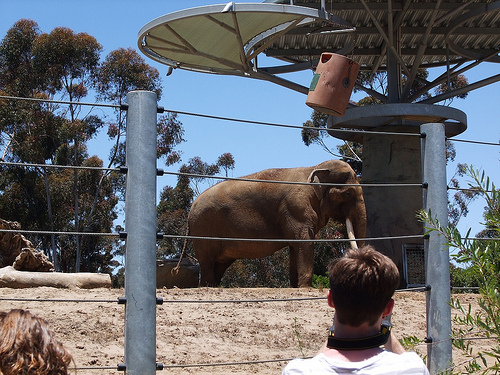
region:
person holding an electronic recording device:
[293, 250, 430, 373]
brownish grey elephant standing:
[182, 160, 364, 279]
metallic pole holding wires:
[113, 86, 165, 372]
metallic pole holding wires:
[421, 120, 451, 374]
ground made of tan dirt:
[165, 285, 285, 372]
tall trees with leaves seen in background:
[2, 19, 121, 262]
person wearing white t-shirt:
[270, 248, 440, 372]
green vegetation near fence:
[443, 158, 498, 370]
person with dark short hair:
[325, 245, 404, 337]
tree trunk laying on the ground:
[1, 261, 112, 291]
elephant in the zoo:
[185, 135, 384, 292]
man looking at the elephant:
[275, 235, 429, 373]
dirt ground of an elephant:
[172, 292, 277, 357]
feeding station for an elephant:
[286, 38, 367, 151]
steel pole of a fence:
[105, 70, 198, 373]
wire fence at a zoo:
[147, 97, 277, 372]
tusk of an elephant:
[339, 214, 362, 247]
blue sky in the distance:
[172, 80, 265, 126]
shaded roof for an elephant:
[128, 6, 325, 90]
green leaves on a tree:
[8, 98, 88, 161]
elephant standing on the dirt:
[156, 145, 408, 302]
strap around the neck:
[316, 326, 403, 358]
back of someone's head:
[1, 305, 83, 373]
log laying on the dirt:
[0, 259, 123, 300]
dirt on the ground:
[0, 279, 497, 371]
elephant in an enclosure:
[1, 42, 498, 372]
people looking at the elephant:
[0, 160, 445, 373]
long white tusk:
[337, 210, 360, 246]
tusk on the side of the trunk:
[340, 203, 374, 258]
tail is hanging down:
[170, 210, 191, 276]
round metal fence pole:
[124, 88, 157, 373]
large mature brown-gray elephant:
[173, 157, 368, 286]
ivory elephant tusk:
[344, 220, 357, 249]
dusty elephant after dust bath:
[170, 160, 366, 287]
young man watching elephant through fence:
[282, 244, 432, 373]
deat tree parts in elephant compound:
[0, 221, 109, 288]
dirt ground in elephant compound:
[0, 287, 498, 373]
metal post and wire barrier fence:
[0, 91, 499, 373]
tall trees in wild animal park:
[1, 0, 233, 286]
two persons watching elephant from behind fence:
[3, 87, 492, 373]